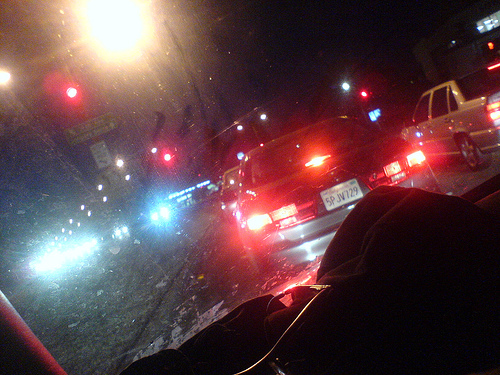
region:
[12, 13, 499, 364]
It is night time.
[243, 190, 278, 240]
The light is red.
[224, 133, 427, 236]
The cars brake lights are on.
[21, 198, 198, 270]
The lights are on.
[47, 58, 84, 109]
The street light is red.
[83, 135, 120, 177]
The sign is white.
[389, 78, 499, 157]
The car is parked.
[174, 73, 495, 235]
The cars are stopped.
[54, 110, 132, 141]
The street sign has white lettering.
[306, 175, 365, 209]
The license is white.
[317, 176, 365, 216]
license plate on the black car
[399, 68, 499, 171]
silver car stopped in traffic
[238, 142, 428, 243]
car's red rear break lights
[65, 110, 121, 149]
green and white street sign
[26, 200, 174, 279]
head lights of oncoming traffic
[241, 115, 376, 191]
rear window of the black car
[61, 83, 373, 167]
three red lights over the intersection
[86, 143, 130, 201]
black and white street signs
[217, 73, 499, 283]
cars stopped at a stop light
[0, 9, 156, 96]
street lights over the intersection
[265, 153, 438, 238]
red taillights on car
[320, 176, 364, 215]
black and white license plate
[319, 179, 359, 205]
black letters on plate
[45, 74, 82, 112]
red traffic light over cars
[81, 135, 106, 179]
white sign under traffic light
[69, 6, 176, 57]
white light above traffic signal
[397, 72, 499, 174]
grey truck next to car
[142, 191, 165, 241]
bright headlights in background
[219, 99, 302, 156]
white lights above car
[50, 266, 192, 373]
pavement is dark grey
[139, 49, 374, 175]
red stop lights over the street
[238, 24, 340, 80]
clear black skies over the road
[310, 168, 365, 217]
a white license plate on a black car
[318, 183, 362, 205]
black lettering on a white license plate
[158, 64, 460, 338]
several cars waiting on a stop light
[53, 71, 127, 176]
a street sign on a pole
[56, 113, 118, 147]
a green street sign on a post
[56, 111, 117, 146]
white lettering on a green sign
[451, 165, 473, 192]
black asphalt surface of the road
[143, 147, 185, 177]
the lights are red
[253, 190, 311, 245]
the lights are red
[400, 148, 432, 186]
the lights are red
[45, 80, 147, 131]
the lights are red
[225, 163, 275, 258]
the lights are red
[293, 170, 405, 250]
the plate number is white